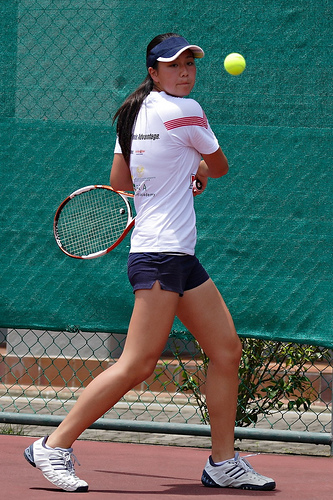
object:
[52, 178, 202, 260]
racket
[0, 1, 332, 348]
cover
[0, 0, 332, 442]
fence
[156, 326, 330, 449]
plant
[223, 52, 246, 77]
tennis ball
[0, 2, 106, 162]
air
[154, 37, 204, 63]
visor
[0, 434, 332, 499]
court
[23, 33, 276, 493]
woman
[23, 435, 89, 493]
shoe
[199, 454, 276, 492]
shoe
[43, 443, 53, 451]
sock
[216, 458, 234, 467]
sock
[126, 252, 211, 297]
shorts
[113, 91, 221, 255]
tee shirt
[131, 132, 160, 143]
words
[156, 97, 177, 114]
white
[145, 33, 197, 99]
head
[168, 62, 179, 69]
eye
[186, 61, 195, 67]
eye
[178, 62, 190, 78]
nose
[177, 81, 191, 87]
mouth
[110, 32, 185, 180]
hair